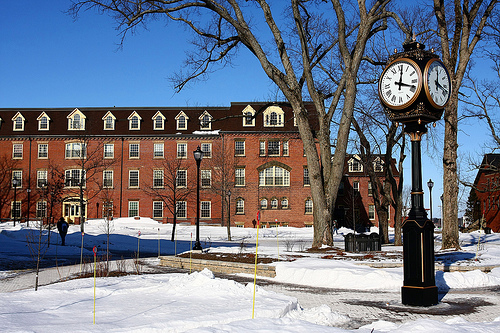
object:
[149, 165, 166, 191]
windows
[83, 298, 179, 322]
shadow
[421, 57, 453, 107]
clock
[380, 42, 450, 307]
tower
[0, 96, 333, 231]
building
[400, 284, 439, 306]
base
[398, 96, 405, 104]
numeral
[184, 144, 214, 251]
pole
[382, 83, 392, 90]
numeral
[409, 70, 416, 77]
numeral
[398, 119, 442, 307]
pole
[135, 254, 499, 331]
sidewalk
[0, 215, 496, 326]
snow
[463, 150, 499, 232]
building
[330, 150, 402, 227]
building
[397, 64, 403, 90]
black hand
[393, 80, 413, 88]
black hand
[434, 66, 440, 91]
black hand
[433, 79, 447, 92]
black hand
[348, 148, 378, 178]
ground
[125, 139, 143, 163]
window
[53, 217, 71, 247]
person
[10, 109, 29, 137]
window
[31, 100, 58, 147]
window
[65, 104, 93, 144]
window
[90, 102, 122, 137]
window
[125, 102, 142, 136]
window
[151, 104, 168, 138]
window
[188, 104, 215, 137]
window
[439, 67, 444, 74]
numeral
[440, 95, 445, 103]
numeral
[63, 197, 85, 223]
doorway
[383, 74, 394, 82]
roman numeral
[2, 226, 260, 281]
shade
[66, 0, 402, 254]
tree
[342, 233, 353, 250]
trashcan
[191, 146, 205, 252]
street light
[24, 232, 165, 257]
sidewalk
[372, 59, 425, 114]
clock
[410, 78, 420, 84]
roman numeral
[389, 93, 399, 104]
roman numeral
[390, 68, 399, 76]
roman numeral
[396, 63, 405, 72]
roman numeral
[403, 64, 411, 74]
roman numeral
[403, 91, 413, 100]
roman numeral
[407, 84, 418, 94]
roman numeral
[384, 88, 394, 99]
roman numeral